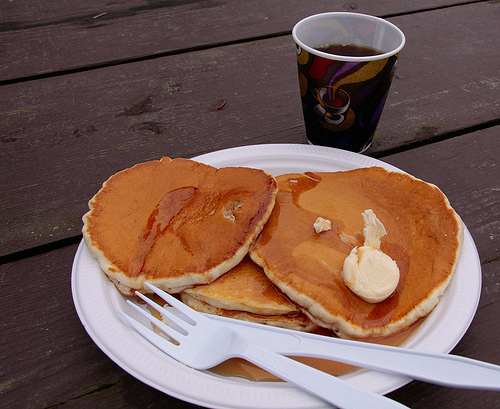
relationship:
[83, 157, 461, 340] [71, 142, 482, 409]
pancakes on top of plate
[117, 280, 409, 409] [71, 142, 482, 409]
fork on top of plate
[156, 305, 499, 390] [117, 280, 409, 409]
knife under fork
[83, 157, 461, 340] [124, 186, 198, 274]
pancakes has syrup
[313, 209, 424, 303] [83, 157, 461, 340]
butter on top of pancake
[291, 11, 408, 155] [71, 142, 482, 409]
cup behind plate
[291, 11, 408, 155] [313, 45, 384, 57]
cup of coffee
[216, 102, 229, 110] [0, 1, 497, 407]
stem on top of table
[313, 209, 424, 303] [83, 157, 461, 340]
butter on top of pancakes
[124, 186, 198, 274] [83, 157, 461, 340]
syrup over pancakes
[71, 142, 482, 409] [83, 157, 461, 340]
plate with pancakes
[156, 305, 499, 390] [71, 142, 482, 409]
knife on top of plate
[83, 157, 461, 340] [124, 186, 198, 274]
pancakes with syrup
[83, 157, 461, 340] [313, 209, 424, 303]
pancakes with butter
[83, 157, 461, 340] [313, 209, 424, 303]
pancake with butter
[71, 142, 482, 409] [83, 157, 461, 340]
plate of pancake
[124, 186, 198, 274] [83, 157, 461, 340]
syrup on top of pancake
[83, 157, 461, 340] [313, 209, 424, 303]
streak of butter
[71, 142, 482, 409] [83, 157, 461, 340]
plate of food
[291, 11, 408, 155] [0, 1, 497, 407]
cup on top of table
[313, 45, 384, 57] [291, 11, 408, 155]
coffee in cup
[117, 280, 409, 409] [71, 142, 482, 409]
fork on plate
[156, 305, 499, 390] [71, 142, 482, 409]
knife on plate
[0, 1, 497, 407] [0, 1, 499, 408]
lines on table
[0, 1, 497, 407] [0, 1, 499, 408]
paint on table